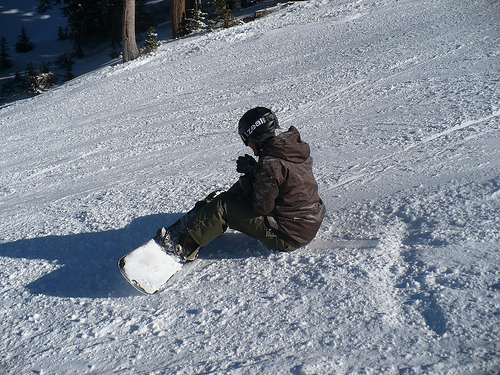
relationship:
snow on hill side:
[2, 0, 498, 375] [0, 0, 498, 372]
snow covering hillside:
[2, 0, 498, 375] [0, 0, 500, 373]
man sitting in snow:
[155, 105, 328, 263] [45, 111, 494, 368]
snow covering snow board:
[120, 238, 183, 294] [127, 183, 238, 290]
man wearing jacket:
[155, 105, 328, 263] [243, 125, 329, 246]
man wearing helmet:
[155, 105, 328, 263] [237, 105, 279, 147]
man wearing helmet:
[155, 105, 328, 263] [232, 105, 281, 147]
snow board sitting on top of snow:
[127, 183, 238, 290] [2, 0, 498, 375]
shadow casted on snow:
[1, 211, 197, 300] [2, 0, 498, 375]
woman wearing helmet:
[153, 103, 326, 264] [229, 108, 280, 152]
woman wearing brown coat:
[153, 103, 326, 264] [233, 128, 324, 242]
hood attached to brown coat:
[261, 126, 312, 162] [237, 125, 327, 247]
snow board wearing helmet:
[127, 183, 238, 290] [213, 87, 298, 147]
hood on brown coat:
[261, 126, 312, 162] [237, 125, 327, 247]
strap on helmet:
[240, 112, 273, 142] [236, 102, 284, 149]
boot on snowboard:
[157, 224, 198, 262] [116, 185, 228, 296]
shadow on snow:
[5, 212, 142, 299] [350, 40, 460, 199]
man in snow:
[155, 105, 328, 263] [356, 25, 481, 265]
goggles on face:
[234, 127, 246, 140] [234, 127, 264, 155]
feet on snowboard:
[157, 220, 199, 262] [116, 185, 228, 296]